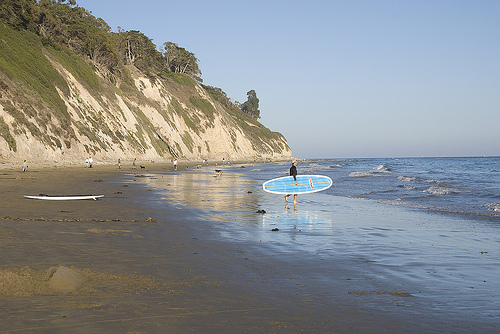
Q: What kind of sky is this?
A: Light blue.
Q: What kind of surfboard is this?
A: Blue and whtie.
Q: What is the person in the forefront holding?
A: A surfboard.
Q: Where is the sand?
A: Next to the water.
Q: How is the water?
A: Choppy.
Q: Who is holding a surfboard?
A: A man,.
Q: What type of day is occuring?
A: A clear day.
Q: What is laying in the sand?
A: A surfboard.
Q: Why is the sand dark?
A: It is wet.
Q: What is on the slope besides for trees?
A: Sand.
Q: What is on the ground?
A: Sand.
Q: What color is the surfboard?
A: Blue.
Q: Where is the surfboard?
A: In the person's hand.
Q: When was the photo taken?
A: Daytime.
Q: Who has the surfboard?
A: The person.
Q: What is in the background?
A: A steep hill.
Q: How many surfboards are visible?
A: Two.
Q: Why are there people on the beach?
A: To go in the water.